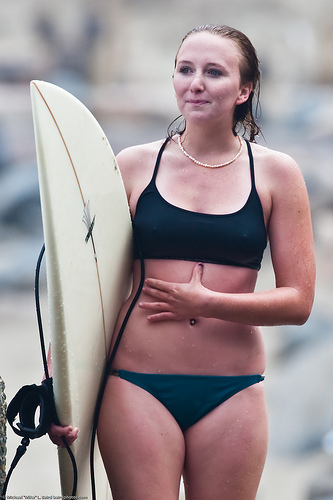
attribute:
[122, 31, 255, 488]
woman — wet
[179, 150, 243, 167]
necklace — necklacey, white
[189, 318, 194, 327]
bellybutton — pierced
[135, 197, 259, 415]
bathing suit — black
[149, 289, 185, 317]
hand — handy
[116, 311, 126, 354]
leash — long, black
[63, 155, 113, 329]
surfboard — wet, white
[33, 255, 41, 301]
strap — black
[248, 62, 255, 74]
hair — dark